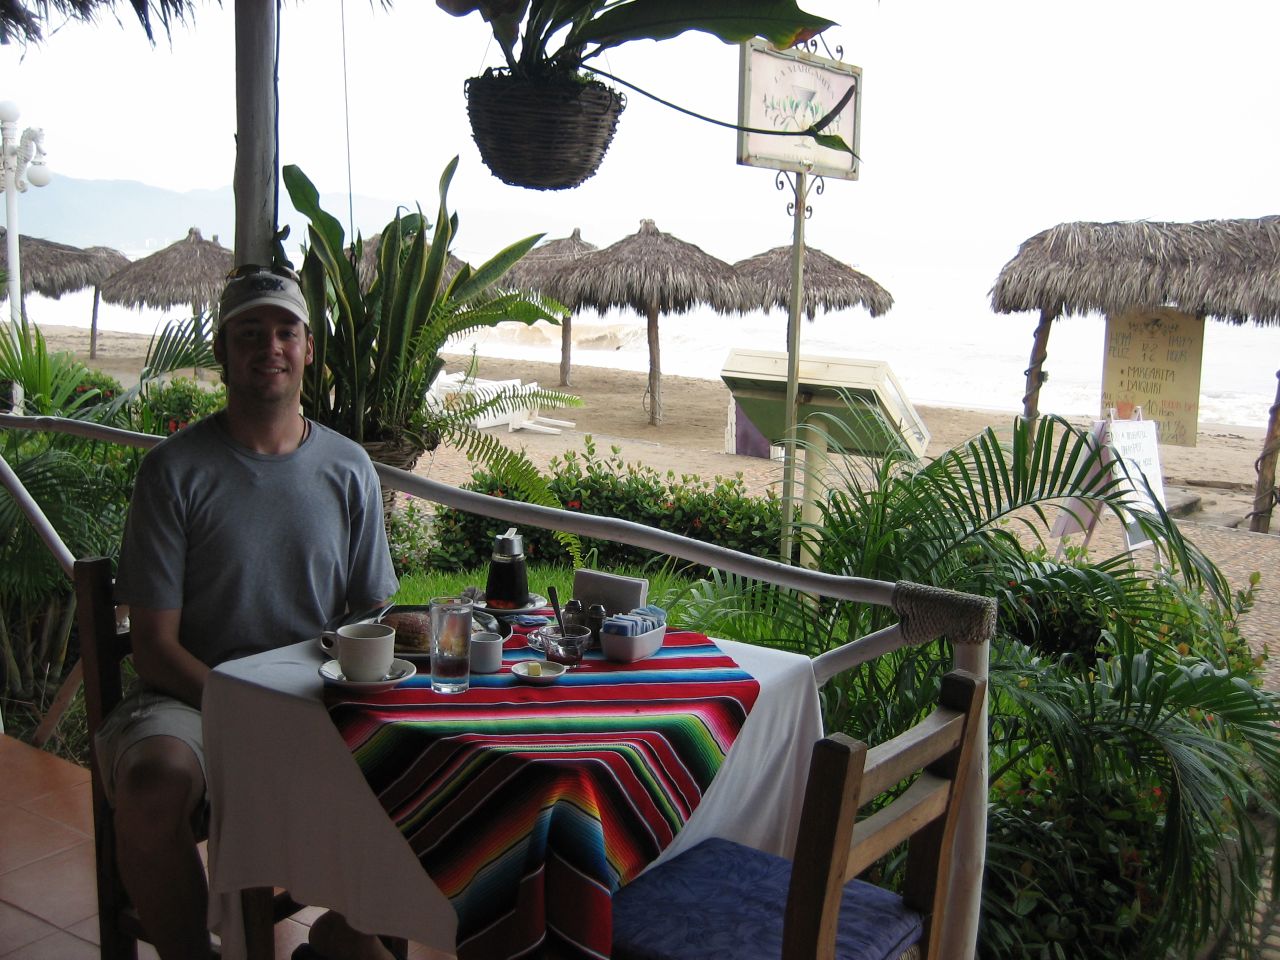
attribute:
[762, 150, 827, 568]
pole — WHITE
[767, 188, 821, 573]
pole — brown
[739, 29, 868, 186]
sign — brown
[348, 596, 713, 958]
cloth — striped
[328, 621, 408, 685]
cups — white, color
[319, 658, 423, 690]
saucer — color, white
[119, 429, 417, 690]
shirt — grey, color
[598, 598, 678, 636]
packets — blue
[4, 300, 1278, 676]
beach — sandy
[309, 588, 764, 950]
cloth — multi-colored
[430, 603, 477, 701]
glass — tall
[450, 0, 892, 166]
plant — green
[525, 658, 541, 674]
butter — quarter square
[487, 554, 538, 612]
syrup — thick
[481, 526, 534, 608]
container — brown, glass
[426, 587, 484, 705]
glass — empty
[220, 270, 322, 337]
cap — white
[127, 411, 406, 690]
shirt — grey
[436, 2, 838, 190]
plant — leafy, green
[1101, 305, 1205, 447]
sign — faded, yellowish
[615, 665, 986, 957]
chair — empty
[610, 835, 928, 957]
seat — blue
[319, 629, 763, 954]
cloth — brightly colored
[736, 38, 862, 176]
sign — rectangular 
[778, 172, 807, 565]
pole — tall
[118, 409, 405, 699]
t-shirt — gray, short-sleeve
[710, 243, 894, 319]
umbrella — round, stationary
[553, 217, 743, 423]
umbrella — round, stationary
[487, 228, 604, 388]
umbrella — round, stationary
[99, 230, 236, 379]
umbrella — round, stationary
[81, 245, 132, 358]
umbrella — round, stationary